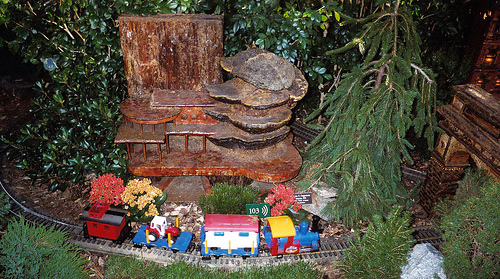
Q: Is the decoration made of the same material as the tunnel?
A: Yes, both the decoration and the tunnel are made of wood.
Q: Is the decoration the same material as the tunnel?
A: Yes, both the decoration and the tunnel are made of wood.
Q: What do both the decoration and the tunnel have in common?
A: The material, both the decoration and the tunnel are wooden.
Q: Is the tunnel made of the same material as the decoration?
A: Yes, both the tunnel and the decoration are made of wood.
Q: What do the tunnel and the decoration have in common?
A: The material, both the tunnel and the decoration are wooden.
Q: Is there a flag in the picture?
A: No, there are no flags.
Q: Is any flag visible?
A: No, there are no flags.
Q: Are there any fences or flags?
A: No, there are no flags or fences.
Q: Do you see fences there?
A: No, there are no fences.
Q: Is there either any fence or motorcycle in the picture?
A: No, there are no fences or motorcycles.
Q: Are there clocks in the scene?
A: No, there are no clocks.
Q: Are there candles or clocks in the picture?
A: No, there are no clocks or candles.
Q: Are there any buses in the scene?
A: No, there are no buses.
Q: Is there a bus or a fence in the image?
A: No, there are no buses or fences.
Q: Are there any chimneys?
A: No, there are no chimneys.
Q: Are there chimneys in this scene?
A: No, there are no chimneys.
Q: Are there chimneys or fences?
A: No, there are no chimneys or fences.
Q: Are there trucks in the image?
A: No, there are no trucks.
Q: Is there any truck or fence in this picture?
A: No, there are no trucks or fences.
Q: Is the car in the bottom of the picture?
A: Yes, the car is in the bottom of the image.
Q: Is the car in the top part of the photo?
A: No, the car is in the bottom of the image.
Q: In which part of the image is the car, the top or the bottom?
A: The car is in the bottom of the image.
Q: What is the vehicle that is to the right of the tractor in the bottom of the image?
A: The vehicle is a car.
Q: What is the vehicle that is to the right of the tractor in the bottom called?
A: The vehicle is a car.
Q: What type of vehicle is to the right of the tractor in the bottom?
A: The vehicle is a car.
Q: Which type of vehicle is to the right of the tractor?
A: The vehicle is a car.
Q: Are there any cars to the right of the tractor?
A: Yes, there is a car to the right of the tractor.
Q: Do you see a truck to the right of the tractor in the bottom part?
A: No, there is a car to the right of the tractor.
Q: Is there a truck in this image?
A: No, there are no trucks.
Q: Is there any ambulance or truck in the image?
A: No, there are no trucks or ambulances.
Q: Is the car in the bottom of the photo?
A: Yes, the car is in the bottom of the image.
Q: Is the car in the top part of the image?
A: No, the car is in the bottom of the image.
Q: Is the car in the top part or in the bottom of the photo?
A: The car is in the bottom of the image.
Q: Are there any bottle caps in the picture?
A: No, there are no bottle caps.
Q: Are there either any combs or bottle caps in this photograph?
A: No, there are no bottle caps or combs.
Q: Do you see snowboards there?
A: No, there are no snowboards.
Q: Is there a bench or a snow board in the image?
A: No, there are no snowboards or benches.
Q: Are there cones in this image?
A: No, there are no cones.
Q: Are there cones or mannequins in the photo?
A: No, there are no cones or mannequins.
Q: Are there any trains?
A: Yes, there is a train.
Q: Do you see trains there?
A: Yes, there is a train.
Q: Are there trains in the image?
A: Yes, there is a train.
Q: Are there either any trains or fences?
A: Yes, there is a train.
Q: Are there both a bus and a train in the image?
A: No, there is a train but no buses.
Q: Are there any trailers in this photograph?
A: No, there are no trailers.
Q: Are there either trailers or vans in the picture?
A: No, there are no trailers or vans.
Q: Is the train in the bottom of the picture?
A: Yes, the train is in the bottom of the image.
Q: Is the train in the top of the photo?
A: No, the train is in the bottom of the image.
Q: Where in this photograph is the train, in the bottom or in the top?
A: The train is in the bottom of the image.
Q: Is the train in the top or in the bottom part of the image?
A: The train is in the bottom of the image.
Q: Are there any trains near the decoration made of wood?
A: Yes, there is a train near the decoration.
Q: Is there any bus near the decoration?
A: No, there is a train near the decoration.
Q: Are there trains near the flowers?
A: Yes, there is a train near the flowers.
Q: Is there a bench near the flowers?
A: No, there is a train near the flowers.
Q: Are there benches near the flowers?
A: No, there is a train near the flowers.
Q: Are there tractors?
A: Yes, there is a tractor.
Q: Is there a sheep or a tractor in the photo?
A: Yes, there is a tractor.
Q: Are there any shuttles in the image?
A: No, there are no shuttles.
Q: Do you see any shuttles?
A: No, there are no shuttles.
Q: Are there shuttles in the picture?
A: No, there are no shuttles.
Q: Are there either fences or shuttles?
A: No, there are no shuttles or fences.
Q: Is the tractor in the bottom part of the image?
A: Yes, the tractor is in the bottom of the image.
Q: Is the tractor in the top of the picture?
A: No, the tractor is in the bottom of the image.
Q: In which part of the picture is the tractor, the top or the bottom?
A: The tractor is in the bottom of the image.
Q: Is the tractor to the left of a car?
A: Yes, the tractor is to the left of a car.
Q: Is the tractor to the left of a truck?
A: No, the tractor is to the left of a car.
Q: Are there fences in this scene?
A: No, there are no fences.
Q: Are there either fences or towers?
A: No, there are no fences or towers.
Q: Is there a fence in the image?
A: No, there are no fences.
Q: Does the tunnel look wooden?
A: Yes, the tunnel is wooden.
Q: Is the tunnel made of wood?
A: Yes, the tunnel is made of wood.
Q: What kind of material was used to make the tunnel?
A: The tunnel is made of wood.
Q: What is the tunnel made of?
A: The tunnel is made of wood.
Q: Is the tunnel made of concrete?
A: No, the tunnel is made of wood.